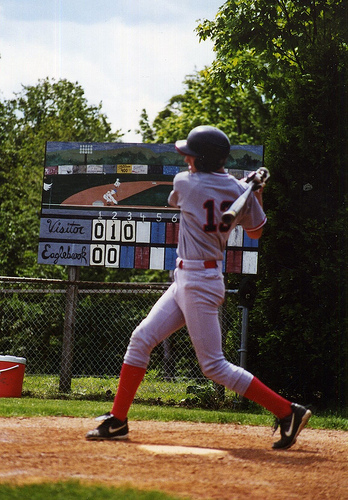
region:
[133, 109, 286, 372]
a young man swinging a baseball bat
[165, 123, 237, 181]
a young man wearing a helmet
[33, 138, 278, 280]
a score board at a baseball field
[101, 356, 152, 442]
a young boy wearing red socks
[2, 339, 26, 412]
a red and white cooler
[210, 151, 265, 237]
a young boy holding a baseball bat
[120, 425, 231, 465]
home plate on a baseball field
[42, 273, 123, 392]
a chain link fence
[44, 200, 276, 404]
a score board on metal post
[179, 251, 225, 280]
a young man wearing a red belt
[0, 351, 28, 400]
A red cooler with a white top and handle.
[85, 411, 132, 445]
A black shoe with a white Nike logo.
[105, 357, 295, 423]
Two red socks on a baseball player.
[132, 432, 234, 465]
A baseball game home plate.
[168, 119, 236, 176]
A baseball helmet on the players head.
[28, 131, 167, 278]
A scoreboard for a baseball game.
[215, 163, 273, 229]
A baseball bat in the players hands.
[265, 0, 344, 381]
Green trees near the baseball field.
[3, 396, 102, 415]
Green grass along the baseball field.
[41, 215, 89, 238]
The word visitor written in black on the scoreboard.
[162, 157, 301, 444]
A boy swinging a bat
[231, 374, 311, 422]
Black and white cleats and orange socks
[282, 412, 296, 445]
A white Nike swoosh on black shoe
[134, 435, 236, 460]
This is home base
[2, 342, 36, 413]
An orange water cooler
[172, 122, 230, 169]
The batter is wearing a black helmet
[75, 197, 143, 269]
The score is 1-0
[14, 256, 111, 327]
A chain link fence under the score board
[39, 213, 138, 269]
The home team is not winning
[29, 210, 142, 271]
The game is in the bottom of the 3rd inning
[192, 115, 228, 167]
boy has black helmet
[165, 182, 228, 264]
black and grey jersey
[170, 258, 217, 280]
boy has orange belt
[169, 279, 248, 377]
boy has grey pants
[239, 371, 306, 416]
boy has orange socks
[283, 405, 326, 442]
black and white shoes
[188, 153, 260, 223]
boy swings black bat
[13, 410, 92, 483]
brown dirt on ground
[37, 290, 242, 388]
chain link fence behind boy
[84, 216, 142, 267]
black numbers on scoreboard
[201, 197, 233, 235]
jersey number 13 for baseball player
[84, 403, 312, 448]
baseball cleats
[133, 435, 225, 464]
plate for homerun and starter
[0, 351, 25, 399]
cooler of drink to quench thirst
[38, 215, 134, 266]
the visitors are winning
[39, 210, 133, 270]
eaglebrook are losing to the visitors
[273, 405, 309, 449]
nike baseball cleat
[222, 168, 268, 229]
bat to hit the ball with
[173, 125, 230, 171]
helmet for shade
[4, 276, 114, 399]
fence to set boundaries